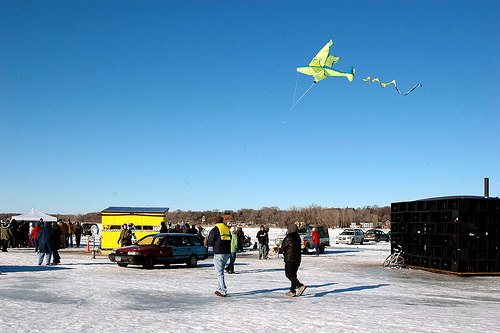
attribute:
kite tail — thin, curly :
[356, 74, 423, 96]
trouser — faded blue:
[213, 252, 230, 294]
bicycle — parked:
[381, 241, 406, 272]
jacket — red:
[311, 230, 318, 246]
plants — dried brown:
[317, 208, 352, 234]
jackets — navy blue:
[276, 229, 306, 269]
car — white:
[337, 227, 367, 254]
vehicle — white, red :
[112, 230, 213, 268]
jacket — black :
[278, 239, 301, 271]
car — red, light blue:
[106, 230, 208, 270]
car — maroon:
[106, 227, 215, 271]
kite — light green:
[293, 39, 425, 99]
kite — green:
[287, 40, 447, 100]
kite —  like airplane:
[290, 36, 428, 96]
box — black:
[386, 192, 485, 279]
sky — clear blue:
[1, 1, 483, 219]